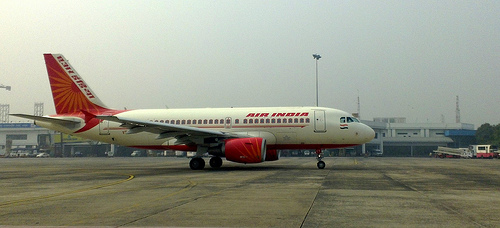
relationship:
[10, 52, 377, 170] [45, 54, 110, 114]
plane has tail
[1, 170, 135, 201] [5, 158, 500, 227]
line painted on ground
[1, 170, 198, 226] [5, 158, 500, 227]
line painted on ground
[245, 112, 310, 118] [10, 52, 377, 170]
lettering painted on plane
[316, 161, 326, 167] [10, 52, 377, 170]
wheel attached under plane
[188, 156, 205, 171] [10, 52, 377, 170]
wheel attached under plane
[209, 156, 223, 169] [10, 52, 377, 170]
wheel attached under plane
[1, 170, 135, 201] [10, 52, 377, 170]
line behind plane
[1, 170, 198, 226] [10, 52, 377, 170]
line behind plane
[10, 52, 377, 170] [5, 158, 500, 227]
plane on top of ground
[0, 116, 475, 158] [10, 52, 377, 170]
building behind plane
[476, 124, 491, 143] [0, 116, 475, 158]
tree next to building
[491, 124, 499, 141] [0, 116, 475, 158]
tree next to building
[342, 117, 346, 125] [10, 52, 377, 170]
window on front of plane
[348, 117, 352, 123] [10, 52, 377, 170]
window on front of plane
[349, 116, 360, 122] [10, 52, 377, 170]
window on front of plane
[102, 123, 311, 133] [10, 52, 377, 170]
line painted on plane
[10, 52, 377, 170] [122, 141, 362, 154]
plane has underside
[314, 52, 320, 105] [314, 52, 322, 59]
pole has light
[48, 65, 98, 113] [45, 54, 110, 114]
design painted on tail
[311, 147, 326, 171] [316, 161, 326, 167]
landing gear has wheel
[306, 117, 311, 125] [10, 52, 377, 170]
window on side of plane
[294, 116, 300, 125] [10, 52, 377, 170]
window on side of plane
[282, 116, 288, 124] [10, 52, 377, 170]
window on side of plane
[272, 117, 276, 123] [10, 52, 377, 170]
window on side of plane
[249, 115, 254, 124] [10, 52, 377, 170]
window on side of plane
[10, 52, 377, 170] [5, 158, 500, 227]
plane parked on ground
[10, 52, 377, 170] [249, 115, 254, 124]
plane has window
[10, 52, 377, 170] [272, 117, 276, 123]
plane has window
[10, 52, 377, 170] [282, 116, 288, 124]
plane has window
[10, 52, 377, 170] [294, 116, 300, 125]
plane has window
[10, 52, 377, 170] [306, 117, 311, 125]
plane has window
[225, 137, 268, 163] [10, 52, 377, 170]
engine attached to plane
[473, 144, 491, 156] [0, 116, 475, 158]
vehicle next to building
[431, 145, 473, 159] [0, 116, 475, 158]
vehicle next to building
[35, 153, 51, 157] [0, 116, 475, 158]
vehicle next to building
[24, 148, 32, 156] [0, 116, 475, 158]
vehicle next to building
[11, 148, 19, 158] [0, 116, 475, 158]
vehicle next to building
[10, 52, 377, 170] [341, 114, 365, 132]
plane has cockpit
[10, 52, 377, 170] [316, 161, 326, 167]
plane has wheel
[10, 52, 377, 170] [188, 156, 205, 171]
plane has wheel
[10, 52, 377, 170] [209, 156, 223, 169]
plane has wheel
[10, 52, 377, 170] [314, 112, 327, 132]
plane has door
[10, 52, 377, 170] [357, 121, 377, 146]
plane has tip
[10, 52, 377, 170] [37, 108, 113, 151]
plane has back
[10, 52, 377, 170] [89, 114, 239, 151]
plane has wing